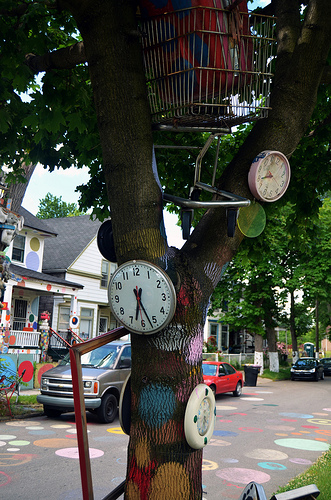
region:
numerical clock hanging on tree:
[104, 258, 185, 336]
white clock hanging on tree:
[126, 336, 219, 498]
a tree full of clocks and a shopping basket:
[16, 113, 330, 494]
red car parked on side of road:
[204, 355, 246, 395]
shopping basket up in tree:
[125, 0, 291, 212]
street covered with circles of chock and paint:
[1, 372, 329, 497]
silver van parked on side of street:
[36, 336, 130, 413]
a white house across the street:
[5, 156, 109, 496]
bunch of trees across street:
[236, 173, 330, 377]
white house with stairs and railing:
[7, 330, 76, 350]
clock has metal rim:
[106, 253, 183, 356]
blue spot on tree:
[140, 382, 165, 426]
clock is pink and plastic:
[252, 143, 295, 210]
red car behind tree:
[205, 336, 255, 413]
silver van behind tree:
[43, 326, 145, 417]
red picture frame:
[50, 323, 154, 491]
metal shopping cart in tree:
[139, 26, 262, 236]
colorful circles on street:
[221, 387, 312, 475]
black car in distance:
[274, 352, 313, 394]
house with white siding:
[46, 251, 106, 351]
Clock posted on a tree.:
[94, 239, 213, 498]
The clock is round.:
[100, 249, 179, 345]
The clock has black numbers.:
[102, 254, 176, 337]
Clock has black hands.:
[102, 252, 175, 340]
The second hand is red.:
[103, 255, 174, 337]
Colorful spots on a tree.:
[94, 228, 231, 498]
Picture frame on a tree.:
[51, 241, 211, 499]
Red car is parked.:
[184, 353, 248, 406]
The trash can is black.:
[233, 357, 274, 395]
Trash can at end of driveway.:
[194, 348, 286, 407]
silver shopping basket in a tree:
[126, 12, 284, 252]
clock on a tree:
[100, 258, 186, 343]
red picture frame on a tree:
[50, 322, 146, 498]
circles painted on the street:
[227, 403, 312, 489]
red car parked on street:
[202, 354, 251, 402]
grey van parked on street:
[34, 338, 129, 426]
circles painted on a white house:
[2, 266, 86, 360]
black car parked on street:
[289, 354, 327, 386]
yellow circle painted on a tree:
[149, 459, 197, 498]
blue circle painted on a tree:
[135, 379, 178, 436]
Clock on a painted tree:
[101, 260, 184, 336]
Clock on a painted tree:
[177, 386, 233, 464]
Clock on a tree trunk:
[241, 146, 289, 207]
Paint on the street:
[225, 383, 303, 472]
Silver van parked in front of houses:
[30, 232, 120, 422]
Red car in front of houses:
[205, 320, 243, 397]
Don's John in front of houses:
[296, 329, 319, 358]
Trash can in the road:
[232, 354, 268, 388]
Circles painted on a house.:
[25, 230, 43, 273]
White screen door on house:
[12, 291, 34, 334]